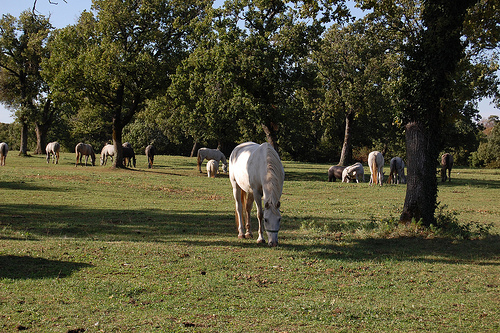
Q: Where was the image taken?
A: It was taken at the field.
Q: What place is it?
A: It is a field.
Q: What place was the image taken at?
A: It was taken at the field.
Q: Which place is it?
A: It is a field.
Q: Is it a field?
A: Yes, it is a field.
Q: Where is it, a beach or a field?
A: It is a field.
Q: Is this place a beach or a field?
A: It is a field.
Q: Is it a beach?
A: No, it is a field.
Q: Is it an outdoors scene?
A: Yes, it is outdoors.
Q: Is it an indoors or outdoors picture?
A: It is outdoors.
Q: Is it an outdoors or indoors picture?
A: It is outdoors.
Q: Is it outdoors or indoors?
A: It is outdoors.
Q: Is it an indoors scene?
A: No, it is outdoors.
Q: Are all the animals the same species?
A: Yes, all the animals are horses.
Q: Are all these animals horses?
A: Yes, all the animals are horses.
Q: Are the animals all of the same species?
A: Yes, all the animals are horses.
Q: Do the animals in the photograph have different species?
A: No, all the animals are horses.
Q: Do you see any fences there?
A: No, there are no fences.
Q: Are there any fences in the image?
A: No, there are no fences.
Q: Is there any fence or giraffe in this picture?
A: No, there are no fences or giraffes.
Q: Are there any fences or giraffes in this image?
A: No, there are no fences or giraffes.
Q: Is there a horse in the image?
A: Yes, there is a horse.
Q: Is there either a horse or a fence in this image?
A: Yes, there is a horse.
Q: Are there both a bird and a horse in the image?
A: No, there is a horse but no birds.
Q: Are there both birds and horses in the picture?
A: No, there is a horse but no birds.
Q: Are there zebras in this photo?
A: No, there are no zebras.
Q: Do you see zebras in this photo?
A: No, there are no zebras.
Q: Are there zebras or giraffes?
A: No, there are no zebras or giraffes.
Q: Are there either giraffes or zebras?
A: No, there are no zebras or giraffes.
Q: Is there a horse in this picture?
A: Yes, there are horses.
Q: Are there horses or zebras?
A: Yes, there are horses.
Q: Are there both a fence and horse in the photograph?
A: No, there are horses but no fences.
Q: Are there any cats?
A: No, there are no cats.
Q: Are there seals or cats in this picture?
A: No, there are no cats or seals.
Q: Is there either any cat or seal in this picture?
A: No, there are no cats or seals.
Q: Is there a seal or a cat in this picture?
A: No, there are no cats or seals.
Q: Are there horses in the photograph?
A: Yes, there is a horse.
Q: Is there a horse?
A: Yes, there is a horse.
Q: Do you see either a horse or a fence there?
A: Yes, there is a horse.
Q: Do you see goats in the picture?
A: No, there are no goats.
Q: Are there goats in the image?
A: No, there are no goats.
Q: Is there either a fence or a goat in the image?
A: No, there are no goats or fences.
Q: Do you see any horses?
A: Yes, there is a horse.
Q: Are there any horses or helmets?
A: Yes, there is a horse.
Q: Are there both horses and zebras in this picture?
A: No, there is a horse but no zebras.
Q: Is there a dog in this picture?
A: No, there are no dogs.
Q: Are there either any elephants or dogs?
A: No, there are no dogs or elephants.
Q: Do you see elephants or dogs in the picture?
A: No, there are no dogs or elephants.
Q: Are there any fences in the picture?
A: No, there are no fences.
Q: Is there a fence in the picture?
A: No, there are no fences.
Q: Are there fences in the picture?
A: No, there are no fences.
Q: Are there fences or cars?
A: No, there are no fences or cars.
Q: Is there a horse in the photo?
A: Yes, there are horses.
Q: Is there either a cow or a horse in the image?
A: Yes, there are horses.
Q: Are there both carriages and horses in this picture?
A: No, there are horses but no carriages.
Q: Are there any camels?
A: No, there are no camels.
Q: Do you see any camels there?
A: No, there are no camels.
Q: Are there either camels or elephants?
A: No, there are no camels or elephants.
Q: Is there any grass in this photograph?
A: Yes, there is grass.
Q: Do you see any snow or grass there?
A: Yes, there is grass.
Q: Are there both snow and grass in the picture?
A: No, there is grass but no snow.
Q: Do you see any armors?
A: No, there are no armors.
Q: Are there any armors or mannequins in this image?
A: No, there are no armors or mannequins.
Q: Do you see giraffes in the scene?
A: No, there are no giraffes.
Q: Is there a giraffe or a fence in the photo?
A: No, there are no giraffes or fences.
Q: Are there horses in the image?
A: Yes, there is a horse.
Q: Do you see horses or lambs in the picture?
A: Yes, there is a horse.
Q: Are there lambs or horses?
A: Yes, there is a horse.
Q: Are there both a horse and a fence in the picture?
A: No, there is a horse but no fences.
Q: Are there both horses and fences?
A: No, there is a horse but no fences.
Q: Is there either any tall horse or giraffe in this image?
A: Yes, there is a tall horse.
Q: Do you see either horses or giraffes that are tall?
A: Yes, the horse is tall.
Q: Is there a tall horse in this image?
A: Yes, there is a tall horse.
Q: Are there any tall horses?
A: Yes, there is a tall horse.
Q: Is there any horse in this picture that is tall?
A: Yes, there is a horse that is tall.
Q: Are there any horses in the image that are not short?
A: Yes, there is a tall horse.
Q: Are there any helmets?
A: No, there are no helmets.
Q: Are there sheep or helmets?
A: No, there are no helmets or sheep.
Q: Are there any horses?
A: Yes, there are horses.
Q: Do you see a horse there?
A: Yes, there are horses.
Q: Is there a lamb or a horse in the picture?
A: Yes, there are horses.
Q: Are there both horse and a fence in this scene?
A: No, there are horses but no fences.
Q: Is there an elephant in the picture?
A: No, there are no elephants.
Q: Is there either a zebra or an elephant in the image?
A: No, there are no elephants or zebras.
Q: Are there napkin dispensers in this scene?
A: No, there are no napkin dispensers.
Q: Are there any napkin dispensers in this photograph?
A: No, there are no napkin dispensers.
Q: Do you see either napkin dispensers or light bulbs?
A: No, there are no napkin dispensers or light bulbs.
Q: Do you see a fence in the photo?
A: No, there are no fences.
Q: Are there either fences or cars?
A: No, there are no fences or cars.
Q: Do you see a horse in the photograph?
A: Yes, there are horses.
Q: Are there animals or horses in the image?
A: Yes, there are horses.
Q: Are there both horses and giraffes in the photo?
A: No, there are horses but no giraffes.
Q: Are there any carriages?
A: No, there are no carriages.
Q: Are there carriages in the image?
A: No, there are no carriages.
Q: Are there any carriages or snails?
A: No, there are no carriages or snails.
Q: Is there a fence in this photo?
A: No, there are no fences.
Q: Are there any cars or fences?
A: No, there are no fences or cars.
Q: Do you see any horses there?
A: Yes, there are horses.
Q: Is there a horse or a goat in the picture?
A: Yes, there are horses.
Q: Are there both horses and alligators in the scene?
A: No, there are horses but no alligators.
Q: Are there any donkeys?
A: No, there are no donkeys.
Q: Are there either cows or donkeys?
A: No, there are no donkeys or cows.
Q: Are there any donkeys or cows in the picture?
A: No, there are no donkeys or cows.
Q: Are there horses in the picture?
A: Yes, there are horses.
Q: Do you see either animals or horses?
A: Yes, there are horses.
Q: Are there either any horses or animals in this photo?
A: Yes, there are horses.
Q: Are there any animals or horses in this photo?
A: Yes, there are horses.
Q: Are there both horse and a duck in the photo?
A: No, there are horses but no ducks.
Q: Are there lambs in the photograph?
A: No, there are no lambs.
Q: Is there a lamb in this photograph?
A: No, there are no lambs.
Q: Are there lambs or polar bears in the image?
A: No, there are no lambs or polar bears.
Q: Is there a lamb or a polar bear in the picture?
A: No, there are no lambs or polar bears.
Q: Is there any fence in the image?
A: No, there are no fences.